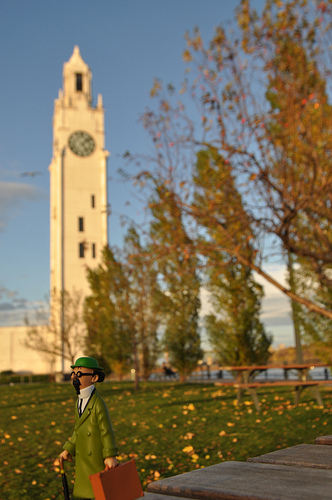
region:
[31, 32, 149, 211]
a large clock tower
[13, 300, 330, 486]
this picture was taken during the fall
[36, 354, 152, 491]
this is not a real person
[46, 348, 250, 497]
this person looks like a toy figurine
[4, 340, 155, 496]
this artificial man is wearing a green coat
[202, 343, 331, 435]
this is a park bench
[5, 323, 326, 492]
This is a toy figue positioned on a park bench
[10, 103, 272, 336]
he sun is shining on this day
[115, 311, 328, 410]
there is water in the background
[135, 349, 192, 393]
there is a barely noticeable person sitting on a bench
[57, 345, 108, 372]
the hat is green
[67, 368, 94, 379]
the glasses are black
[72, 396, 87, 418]
the tie is black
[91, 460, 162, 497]
the suitcase is rectangular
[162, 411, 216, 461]
the leaves are on the grass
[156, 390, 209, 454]
the leaves are yellow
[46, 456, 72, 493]
the umbrella is black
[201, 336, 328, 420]
the picnic table is wooden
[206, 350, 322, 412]
the table is brown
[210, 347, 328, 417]
the table is in the grass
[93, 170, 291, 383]
the trees are visible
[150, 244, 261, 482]
the trees are visible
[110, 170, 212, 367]
the trees are visible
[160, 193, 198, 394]
the trees are visible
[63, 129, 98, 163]
clock on tall tower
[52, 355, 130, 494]
toy figurine on sidewalk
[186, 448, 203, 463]
leaves in green grass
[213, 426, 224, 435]
leaves in green grass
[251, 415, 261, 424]
leaves in green grass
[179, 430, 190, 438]
leaves in green grass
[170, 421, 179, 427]
leaves in green grass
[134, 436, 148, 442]
leaves in green grass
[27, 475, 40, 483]
leaves in green grass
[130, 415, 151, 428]
leaves in green grass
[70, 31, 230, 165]
the sky is white and visible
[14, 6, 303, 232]
the sky is white and visible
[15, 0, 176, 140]
the sky is white and visible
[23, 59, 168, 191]
the sky is white and visible